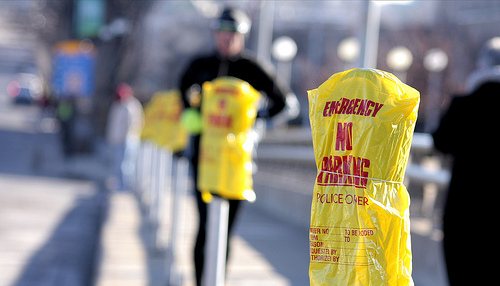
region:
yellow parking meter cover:
[254, 47, 439, 281]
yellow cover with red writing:
[301, 90, 396, 214]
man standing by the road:
[162, 3, 304, 277]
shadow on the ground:
[45, 166, 114, 281]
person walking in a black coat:
[415, 26, 496, 258]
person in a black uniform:
[164, 27, 286, 207]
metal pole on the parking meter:
[196, 187, 230, 282]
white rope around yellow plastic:
[295, 145, 419, 201]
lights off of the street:
[370, 26, 440, 91]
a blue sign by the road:
[7, 17, 114, 142]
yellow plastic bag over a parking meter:
[292, 63, 443, 285]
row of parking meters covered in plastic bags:
[132, 56, 413, 284]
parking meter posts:
[135, 146, 254, 284]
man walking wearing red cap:
[105, 79, 153, 187]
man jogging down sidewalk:
[171, 6, 297, 284]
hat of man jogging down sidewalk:
[208, 4, 251, 40]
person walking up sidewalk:
[430, 29, 496, 284]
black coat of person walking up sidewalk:
[441, 76, 498, 274]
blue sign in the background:
[40, 41, 99, 115]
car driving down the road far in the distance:
[3, 66, 43, 110]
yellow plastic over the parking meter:
[275, 62, 442, 270]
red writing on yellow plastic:
[304, 88, 391, 225]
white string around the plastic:
[312, 148, 420, 208]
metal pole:
[191, 182, 233, 282]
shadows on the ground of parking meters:
[6, 150, 149, 282]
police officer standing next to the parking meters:
[147, 5, 292, 283]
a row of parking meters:
[122, 70, 440, 285]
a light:
[270, 27, 307, 82]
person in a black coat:
[422, 14, 497, 284]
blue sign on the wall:
[45, 37, 120, 122]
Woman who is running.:
[119, 1, 359, 247]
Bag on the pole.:
[288, 21, 440, 283]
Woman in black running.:
[144, 18, 390, 282]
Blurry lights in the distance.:
[251, 22, 420, 144]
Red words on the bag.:
[269, 87, 424, 222]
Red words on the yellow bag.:
[273, 70, 477, 237]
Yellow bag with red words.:
[288, 57, 429, 271]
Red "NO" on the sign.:
[333, 106, 360, 153]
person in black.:
[385, 40, 499, 257]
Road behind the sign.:
[68, 179, 171, 271]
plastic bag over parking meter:
[296, 58, 416, 285]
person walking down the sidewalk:
[179, 4, 280, 284]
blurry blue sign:
[41, 33, 102, 111]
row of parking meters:
[126, 73, 426, 284]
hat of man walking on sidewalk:
[198, 7, 258, 37]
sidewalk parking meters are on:
[105, 156, 282, 285]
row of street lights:
[268, 26, 499, 71]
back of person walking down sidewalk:
[439, 32, 496, 284]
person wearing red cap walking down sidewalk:
[100, 81, 154, 186]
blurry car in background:
[2, 66, 42, 106]